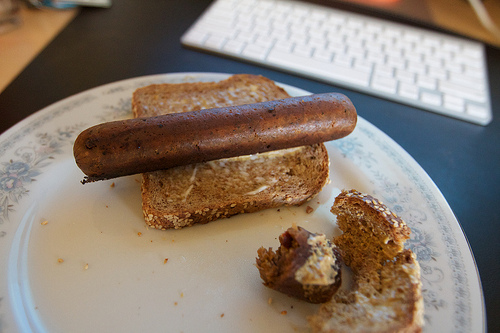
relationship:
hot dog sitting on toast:
[73, 91, 358, 181] [131, 72, 330, 230]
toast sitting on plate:
[131, 72, 330, 230] [0, 71, 489, 332]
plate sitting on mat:
[0, 71, 489, 332] [0, 0, 499, 331]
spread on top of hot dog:
[294, 231, 340, 285] [255, 225, 342, 305]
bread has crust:
[306, 187, 425, 332] [333, 188, 409, 230]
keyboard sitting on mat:
[178, 0, 492, 127] [0, 0, 499, 331]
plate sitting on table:
[0, 71, 489, 332] [0, 0, 500, 332]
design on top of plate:
[329, 134, 447, 326] [0, 71, 489, 332]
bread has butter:
[306, 187, 425, 332] [321, 290, 411, 332]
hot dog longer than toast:
[73, 91, 358, 181] [131, 72, 330, 230]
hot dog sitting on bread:
[255, 225, 342, 305] [306, 187, 425, 332]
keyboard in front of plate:
[178, 0, 492, 127] [0, 71, 489, 332]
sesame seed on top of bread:
[384, 209, 391, 215] [306, 187, 425, 332]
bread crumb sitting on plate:
[304, 204, 315, 214] [0, 71, 489, 332]